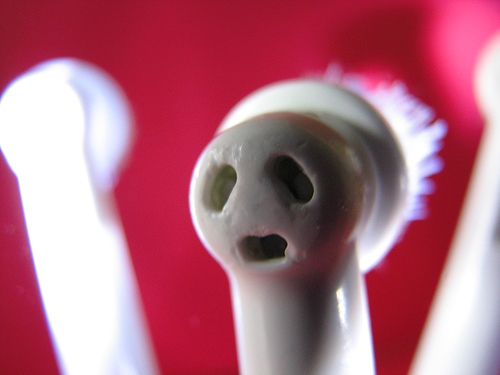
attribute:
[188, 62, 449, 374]
toothbrush — electric, white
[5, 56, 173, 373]
brush — different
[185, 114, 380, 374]
model — cray, white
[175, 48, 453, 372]
brush — round, tooth, electric, white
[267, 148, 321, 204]
hole — oblong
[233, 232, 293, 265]
hole — oblong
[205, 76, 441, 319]
white brush — ceramic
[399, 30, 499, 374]
object — blurry, on the right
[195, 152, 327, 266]
face — bumpy, plastic , light-created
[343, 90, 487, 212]
bristles — round, white, blue-tipped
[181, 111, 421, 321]
toothbrush — electric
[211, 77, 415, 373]
toothbrush — electric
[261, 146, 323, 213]
hole — face-creating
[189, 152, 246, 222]
hole — face-creating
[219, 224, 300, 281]
hole — face-creating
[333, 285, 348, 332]
reflection — on side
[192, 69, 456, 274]
spinbrush head — off-white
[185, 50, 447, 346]
brush — white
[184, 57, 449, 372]
model — cray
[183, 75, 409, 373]
brush — pictured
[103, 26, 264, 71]
red — lipstick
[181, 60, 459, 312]
brush — featured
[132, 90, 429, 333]
light — shining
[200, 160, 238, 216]
hole — oblong, oval, chipped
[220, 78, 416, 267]
front — round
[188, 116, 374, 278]
back end — round, smaller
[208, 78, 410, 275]
head — round